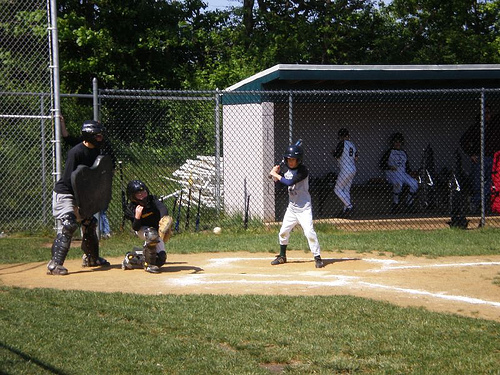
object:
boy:
[272, 141, 331, 273]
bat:
[268, 140, 302, 180]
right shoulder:
[269, 163, 311, 186]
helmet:
[285, 146, 306, 162]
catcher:
[124, 183, 178, 272]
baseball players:
[333, 127, 499, 213]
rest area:
[272, 99, 500, 217]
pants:
[280, 209, 322, 257]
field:
[9, 234, 497, 375]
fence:
[7, 91, 498, 239]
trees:
[9, 5, 495, 61]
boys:
[38, 127, 328, 272]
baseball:
[210, 226, 226, 236]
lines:
[360, 276, 500, 318]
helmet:
[77, 113, 107, 141]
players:
[279, 173, 323, 256]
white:
[281, 172, 323, 257]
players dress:
[54, 146, 110, 195]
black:
[126, 197, 171, 228]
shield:
[67, 157, 122, 219]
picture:
[5, 6, 495, 315]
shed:
[217, 95, 279, 225]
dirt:
[366, 236, 500, 325]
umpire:
[51, 112, 116, 279]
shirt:
[281, 170, 320, 212]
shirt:
[340, 143, 358, 209]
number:
[347, 140, 357, 159]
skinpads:
[144, 228, 166, 250]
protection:
[142, 221, 173, 255]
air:
[185, 170, 260, 202]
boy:
[389, 133, 420, 206]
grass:
[9, 289, 476, 375]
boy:
[116, 179, 171, 275]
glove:
[154, 213, 177, 242]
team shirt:
[281, 170, 320, 251]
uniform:
[267, 168, 331, 245]